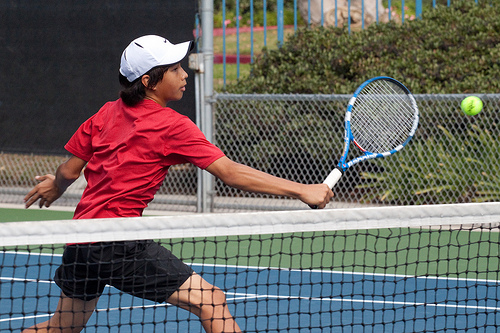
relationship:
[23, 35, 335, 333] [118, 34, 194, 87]
boy wearing cap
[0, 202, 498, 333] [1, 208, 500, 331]
net situated on tennis court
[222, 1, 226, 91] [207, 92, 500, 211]
post sitting on fence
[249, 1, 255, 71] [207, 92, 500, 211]
post sitting on fence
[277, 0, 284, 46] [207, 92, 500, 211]
post sitting on fence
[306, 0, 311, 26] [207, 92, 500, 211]
post sitting on fence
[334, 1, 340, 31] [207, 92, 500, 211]
post sitting on fence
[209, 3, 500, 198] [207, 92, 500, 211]
bush in front of fence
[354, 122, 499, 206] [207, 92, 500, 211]
bush in front of fence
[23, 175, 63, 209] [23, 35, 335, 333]
hand of boy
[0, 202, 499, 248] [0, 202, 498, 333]
edge on top of net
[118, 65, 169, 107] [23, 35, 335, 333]
hair of boy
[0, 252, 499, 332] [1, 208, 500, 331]
part of tennis court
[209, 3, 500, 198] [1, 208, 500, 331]
bush next to tennis court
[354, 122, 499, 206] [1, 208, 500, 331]
bush next to tennis court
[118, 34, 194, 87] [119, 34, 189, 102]
cap sitting on head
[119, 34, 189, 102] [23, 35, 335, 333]
head of boy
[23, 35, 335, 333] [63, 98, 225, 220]
boy wearing shirt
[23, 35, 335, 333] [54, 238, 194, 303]
boy wearing shorts